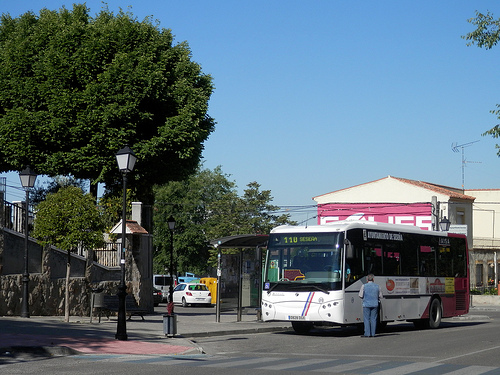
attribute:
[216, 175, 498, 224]
clouds — white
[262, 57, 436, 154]
clouds — white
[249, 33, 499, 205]
sky — blue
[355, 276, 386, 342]
person — blue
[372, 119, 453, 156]
clouds — white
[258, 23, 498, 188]
sky — blue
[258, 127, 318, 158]
cloud — white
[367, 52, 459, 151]
sky — blue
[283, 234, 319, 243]
read out — digital, green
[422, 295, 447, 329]
tire — rubber, black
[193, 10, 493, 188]
sky — blue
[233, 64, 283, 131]
clouds — white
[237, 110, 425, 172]
clouds — white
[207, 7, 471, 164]
sky — blue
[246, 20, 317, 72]
clouds — white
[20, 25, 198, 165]
tree — tall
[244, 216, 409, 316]
bus — transit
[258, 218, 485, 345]
bus — white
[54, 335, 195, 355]
sidewalk — red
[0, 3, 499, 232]
sky — blue,  blue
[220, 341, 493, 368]
road — paved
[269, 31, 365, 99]
sky — blue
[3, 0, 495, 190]
clouds — white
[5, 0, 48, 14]
clouds —  white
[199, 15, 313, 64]
sky — blue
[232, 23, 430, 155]
sky — blue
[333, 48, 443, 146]
clouds — white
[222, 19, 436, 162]
clouds — white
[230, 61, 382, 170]
sky — blue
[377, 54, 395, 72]
cloud — white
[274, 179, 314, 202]
cloud — white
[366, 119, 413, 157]
cloud — white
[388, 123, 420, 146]
cloud — white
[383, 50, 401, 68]
cloud — white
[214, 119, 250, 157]
cloud — white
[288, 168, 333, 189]
cloud — white